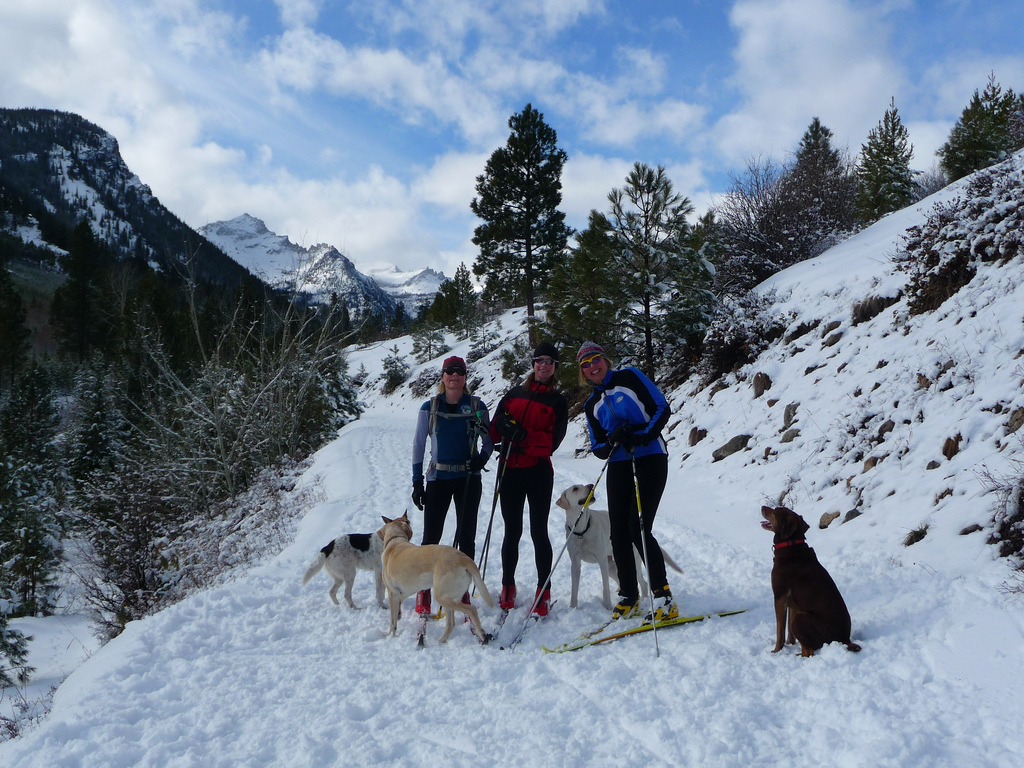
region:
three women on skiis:
[405, 344, 756, 665]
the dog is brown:
[759, 505, 870, 665]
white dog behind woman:
[549, 481, 685, 606]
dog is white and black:
[297, 514, 414, 614]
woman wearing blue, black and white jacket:
[574, 332, 683, 626]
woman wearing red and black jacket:
[483, 338, 572, 626]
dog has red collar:
[752, 502, 864, 677]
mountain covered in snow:
[190, 203, 472, 346]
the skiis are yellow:
[531, 598, 775, 660]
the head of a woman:
[419, 344, 481, 409]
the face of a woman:
[423, 315, 503, 414]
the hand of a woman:
[388, 463, 446, 528]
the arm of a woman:
[389, 384, 435, 515]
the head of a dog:
[562, 458, 619, 523]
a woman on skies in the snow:
[450, 301, 600, 671]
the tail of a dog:
[455, 546, 514, 649]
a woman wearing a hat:
[493, 322, 589, 405]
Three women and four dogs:
[298, 333, 874, 670]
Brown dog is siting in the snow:
[748, 498, 865, 664]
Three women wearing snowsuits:
[399, 334, 751, 664]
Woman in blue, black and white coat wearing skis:
[538, 334, 763, 664]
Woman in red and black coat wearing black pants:
[482, 333, 574, 613]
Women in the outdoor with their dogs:
[4, 1, 1022, 766]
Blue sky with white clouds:
[0, 1, 1019, 271]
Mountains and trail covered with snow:
[0, 102, 1016, 766]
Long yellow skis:
[535, 592, 761, 665]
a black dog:
[750, 492, 871, 680]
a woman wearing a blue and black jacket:
[564, 330, 688, 641]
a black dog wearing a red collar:
[744, 494, 869, 675]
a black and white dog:
[294, 500, 413, 621]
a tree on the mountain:
[457, 93, 581, 338]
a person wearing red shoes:
[484, 337, 577, 628]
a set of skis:
[551, 598, 760, 665]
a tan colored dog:
[367, 504, 511, 654]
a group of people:
[400, 324, 686, 637]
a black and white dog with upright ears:
[302, 509, 420, 623]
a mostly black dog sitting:
[754, 500, 866, 666]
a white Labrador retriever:
[556, 481, 690, 624]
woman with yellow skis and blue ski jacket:
[568, 338, 756, 675]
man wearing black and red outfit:
[489, 335, 576, 643]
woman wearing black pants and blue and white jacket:
[408, 351, 498, 628]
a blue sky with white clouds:
[5, 7, 1023, 301]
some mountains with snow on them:
[2, 99, 468, 660]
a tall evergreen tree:
[467, 98, 579, 351]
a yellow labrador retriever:
[376, 518, 509, 661]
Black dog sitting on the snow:
[754, 503, 862, 658]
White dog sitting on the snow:
[551, 478, 684, 615]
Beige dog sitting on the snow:
[374, 524, 493, 643]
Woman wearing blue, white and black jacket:
[567, 342, 689, 628]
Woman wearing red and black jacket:
[487, 345, 563, 617]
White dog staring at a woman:
[551, 474, 689, 612]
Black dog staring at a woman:
[751, 500, 869, 657]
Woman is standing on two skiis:
[567, 344, 688, 635]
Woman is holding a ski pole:
[481, 341, 568, 620]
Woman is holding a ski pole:
[566, 334, 680, 630]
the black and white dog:
[304, 509, 416, 608]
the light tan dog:
[555, 481, 683, 611]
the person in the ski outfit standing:
[409, 349, 487, 625]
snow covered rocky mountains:
[191, 213, 468, 327]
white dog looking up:
[557, 483, 606, 610]